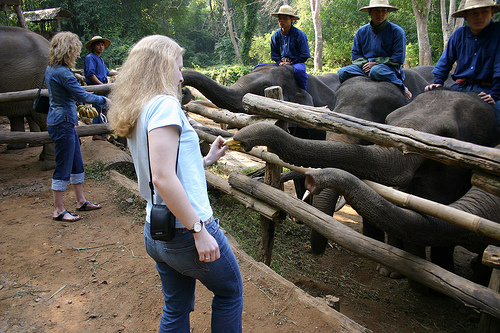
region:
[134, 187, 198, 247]
This is a camera, probably digital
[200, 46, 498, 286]
Four young elephants are eating peanuts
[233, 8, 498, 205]
Young men are riding young elephants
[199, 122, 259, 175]
Tourists are feeding elephants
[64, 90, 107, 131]
The elephants are eating bananas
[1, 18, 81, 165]
This is a full grown elephant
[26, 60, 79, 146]
The woman is carrying a purse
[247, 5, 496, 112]
These young men look oriental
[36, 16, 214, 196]
These tourists look anglo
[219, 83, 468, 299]
This fence is made of wooden logs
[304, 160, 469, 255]
elephant trunk reaching out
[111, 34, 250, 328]
girl with camera with strap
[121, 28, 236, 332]
blonde haired girl with camera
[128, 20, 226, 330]
woman feeding elephant food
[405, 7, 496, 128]
man in blue riding elephant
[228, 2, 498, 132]
three men riding elephants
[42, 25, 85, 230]
women in background with purse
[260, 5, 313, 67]
man in blue with hat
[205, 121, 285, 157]
hand feeding elephant trunk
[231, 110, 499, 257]
reaching elephant trunks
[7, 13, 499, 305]
People feeding small elephants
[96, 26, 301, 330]
a woman feeding an elephant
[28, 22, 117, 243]
a woman standing in the dirt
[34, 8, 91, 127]
A woman in a jean shirt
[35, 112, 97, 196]
A woman wearing jean capris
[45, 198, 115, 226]
A woman wearing flip flops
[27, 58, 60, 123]
A woman carrying a purse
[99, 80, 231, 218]
A woman wearing a t-shirt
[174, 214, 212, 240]
A woman wearing a watch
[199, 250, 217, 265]
A ring on a woman's finger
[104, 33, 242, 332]
A women is feeding the elephant.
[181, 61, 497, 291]
There three elephants in the zoo.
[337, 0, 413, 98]
The man has a hat.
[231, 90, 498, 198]
The elephant is eating from the lady's hand.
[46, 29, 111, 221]
The woman has a blond hair.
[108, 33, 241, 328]
The woman has a camera in his right shoulder.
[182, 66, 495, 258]
Three elephants are behind the fence.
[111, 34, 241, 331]
The woman is wearing a blue jeans and light blue t-shirt.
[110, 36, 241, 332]
The woman has a watch is her right hand.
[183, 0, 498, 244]
The elephants has a man on its back.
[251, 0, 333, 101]
a person sitting on an elephant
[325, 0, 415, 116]
a person sitting on an elephant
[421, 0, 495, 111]
a person sitting on an elephant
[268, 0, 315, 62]
a person wearing a blue shirt and a brimmed hat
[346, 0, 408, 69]
a person wearing a blue shirt and a brimmed hat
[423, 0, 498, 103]
a person wearing a blue shirt and a brimmed hat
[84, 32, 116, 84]
a person wearing a blue shirt and a brimmed hat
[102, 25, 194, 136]
a woman with long blonde hair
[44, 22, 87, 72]
a woman with curly hair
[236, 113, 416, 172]
the trunk of an elephant